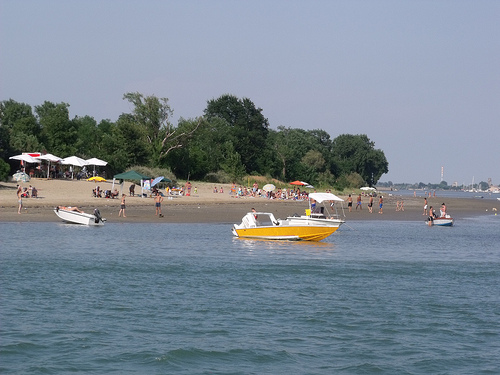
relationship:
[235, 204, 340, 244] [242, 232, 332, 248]
motor boat with hull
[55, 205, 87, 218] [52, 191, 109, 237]
woman laying on white boat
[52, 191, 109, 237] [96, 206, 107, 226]
white boat with black outboard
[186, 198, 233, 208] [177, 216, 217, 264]
sand by water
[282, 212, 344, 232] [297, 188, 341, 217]
white boat with sunshade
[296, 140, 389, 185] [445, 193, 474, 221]
trees near beach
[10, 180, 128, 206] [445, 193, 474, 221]
people on beach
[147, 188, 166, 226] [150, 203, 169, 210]
man in blue trunks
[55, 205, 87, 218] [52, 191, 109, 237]
woman on white boat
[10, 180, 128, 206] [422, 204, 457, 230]
people on boat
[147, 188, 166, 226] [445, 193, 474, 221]
man on beach